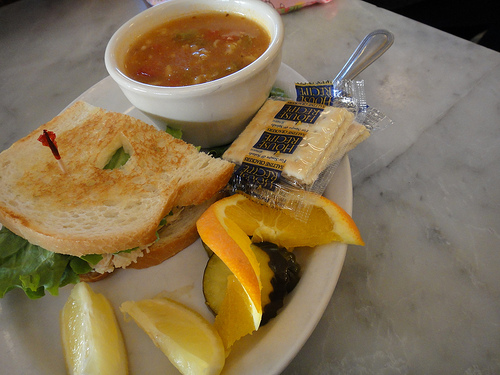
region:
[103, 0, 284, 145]
Small white bowl of vegetable soup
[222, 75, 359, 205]
Plastic packets of saltine crackers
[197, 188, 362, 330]
Twisted slice of an orange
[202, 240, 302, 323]
Round slice of a pickle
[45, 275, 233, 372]
Two sliced lemon wedges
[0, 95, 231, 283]
Tuna fish sandwich on toasted white bread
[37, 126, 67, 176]
Toothpick with plastic red curls on end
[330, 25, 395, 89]
End of a silver spoon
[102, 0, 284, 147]
Tomato based soup in bowl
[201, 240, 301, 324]
Chunky slice of dill pickle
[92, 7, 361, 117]
Dark soup in bowl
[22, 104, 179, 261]
Golden brown toast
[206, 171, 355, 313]
Yellow lemon on plate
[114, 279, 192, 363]
Yellow lemon on plate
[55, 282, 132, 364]
Yellow lemon on plate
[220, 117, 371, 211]
Small pack of crackers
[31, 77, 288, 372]
large Plate of food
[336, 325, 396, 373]
White marble counter top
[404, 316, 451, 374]
White marble counter top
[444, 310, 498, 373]
White marble counter top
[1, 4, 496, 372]
surface of gray marble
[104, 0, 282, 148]
soup in white bowl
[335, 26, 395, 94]
silver metal utensil handle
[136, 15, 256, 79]
vegetables inside of soup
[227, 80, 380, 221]
crackers in plastic wrap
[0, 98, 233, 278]
toasted bread on sandwich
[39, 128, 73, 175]
red tip of toothbrush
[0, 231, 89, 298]
green lettuce of sandwich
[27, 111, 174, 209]
brown of toasted bread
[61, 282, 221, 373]
two lemon slices on plate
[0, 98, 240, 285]
toasted sandwich on a plate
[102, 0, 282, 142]
soup in a bowl on a plate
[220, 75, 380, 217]
soup crackers wrapped in plastic wrapper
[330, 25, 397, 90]
edge of a soup spoon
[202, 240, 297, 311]
sliced pickles under a slice of orange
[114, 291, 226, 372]
slice of lemon on a plate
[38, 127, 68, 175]
toothpick with red plastic in a sandwich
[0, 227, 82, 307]
green lettuce hanging out of a sandwich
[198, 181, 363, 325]
slice of orange on a plate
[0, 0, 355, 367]
soup and sandwich lunch on a plate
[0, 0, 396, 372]
food on a plate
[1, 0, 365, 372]
the plate is white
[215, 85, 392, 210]
crackers are on the plate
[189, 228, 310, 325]
2 pickles on the plate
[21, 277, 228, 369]
lemon wedges on the plate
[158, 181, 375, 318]
a piece of an orange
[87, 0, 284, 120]
a cup of soup on the plate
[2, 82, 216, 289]
a piece of a sandwich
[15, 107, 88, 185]
a toothpick in the bread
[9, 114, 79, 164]
tip of the toothpick is red